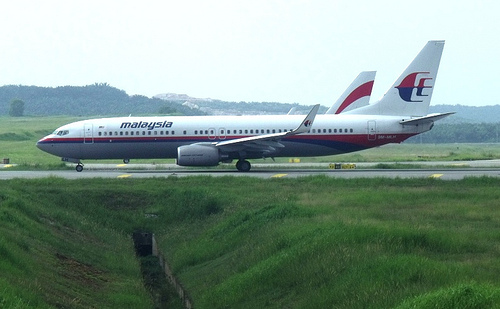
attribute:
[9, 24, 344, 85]
sky — blue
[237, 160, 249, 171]
wheel — black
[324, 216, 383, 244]
grass — green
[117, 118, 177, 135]
word — black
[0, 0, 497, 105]
sky — cloudy, white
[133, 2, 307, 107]
sky — clear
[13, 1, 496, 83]
sky — clear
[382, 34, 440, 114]
tail — red, white, blue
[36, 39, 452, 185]
aircraft — moving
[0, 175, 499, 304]
thick grass — green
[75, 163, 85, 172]
wheel — round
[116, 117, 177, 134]
owner identification — airline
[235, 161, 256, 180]
wheel — black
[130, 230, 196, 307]
ditch — irrigation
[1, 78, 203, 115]
trees — green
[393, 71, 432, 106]
logo — blue, red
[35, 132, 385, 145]
stripes — blue, red